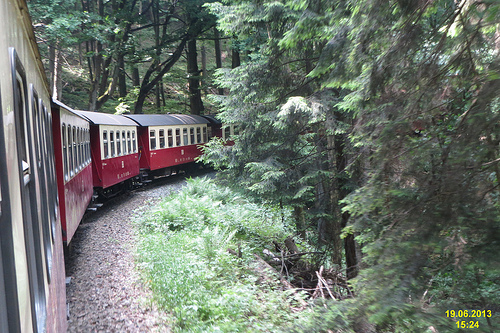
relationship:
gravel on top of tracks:
[90, 184, 173, 331] [98, 169, 205, 200]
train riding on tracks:
[2, 2, 217, 311] [66, 154, 200, 262]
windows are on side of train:
[101, 118, 215, 152] [2, 2, 217, 311]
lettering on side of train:
[446, 307, 490, 331] [2, 2, 217, 311]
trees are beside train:
[201, 2, 496, 318] [2, 2, 217, 311]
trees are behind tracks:
[201, 2, 496, 318] [98, 169, 205, 200]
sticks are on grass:
[278, 237, 350, 321] [160, 172, 369, 332]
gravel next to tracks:
[90, 184, 173, 331] [66, 154, 200, 262]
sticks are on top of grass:
[278, 237, 350, 321] [160, 172, 369, 332]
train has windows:
[2, 2, 217, 311] [101, 118, 215, 152]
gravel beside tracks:
[90, 184, 173, 331] [66, 154, 200, 262]